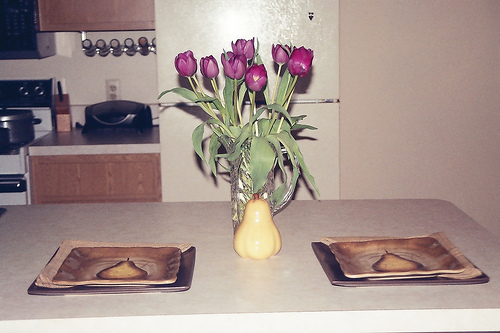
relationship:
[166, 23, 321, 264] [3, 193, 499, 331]
flowers on a table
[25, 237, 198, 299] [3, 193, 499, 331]
plate on a table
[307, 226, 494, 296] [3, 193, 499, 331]
plate on a table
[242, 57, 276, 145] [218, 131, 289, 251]
flower in a vase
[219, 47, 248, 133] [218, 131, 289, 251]
flower in a vase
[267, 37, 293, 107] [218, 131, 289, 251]
flower in a vase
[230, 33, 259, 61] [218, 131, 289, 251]
flower in a vase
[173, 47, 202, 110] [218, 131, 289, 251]
flower in a vase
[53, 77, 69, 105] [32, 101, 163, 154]
knife on a counter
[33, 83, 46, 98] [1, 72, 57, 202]
knob on a stove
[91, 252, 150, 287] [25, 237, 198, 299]
pear on plate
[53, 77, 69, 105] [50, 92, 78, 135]
knives in wooden block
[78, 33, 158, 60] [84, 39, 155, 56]
rack with spices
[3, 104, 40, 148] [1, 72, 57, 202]
pot on top of stove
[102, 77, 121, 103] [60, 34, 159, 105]
electric outlet on wall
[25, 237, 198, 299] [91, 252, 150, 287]
plate with pear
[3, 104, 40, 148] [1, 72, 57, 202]
pot on top stove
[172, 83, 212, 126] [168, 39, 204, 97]
stem of flower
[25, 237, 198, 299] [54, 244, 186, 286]
plate with napkin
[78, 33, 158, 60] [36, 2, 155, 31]
rack under cabinet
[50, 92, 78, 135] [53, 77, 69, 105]
holder with single knife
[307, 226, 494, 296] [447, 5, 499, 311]
plate on right side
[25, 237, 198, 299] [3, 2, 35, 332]
plate on left side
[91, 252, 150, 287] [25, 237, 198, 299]
pear in left plate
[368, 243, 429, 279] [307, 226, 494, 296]
pear in right plate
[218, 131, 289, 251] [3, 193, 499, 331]
vase on table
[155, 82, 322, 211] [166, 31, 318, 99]
leaves under roses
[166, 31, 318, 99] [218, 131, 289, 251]
roses sprouting out vase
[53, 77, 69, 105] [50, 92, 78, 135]
knife on knife holder